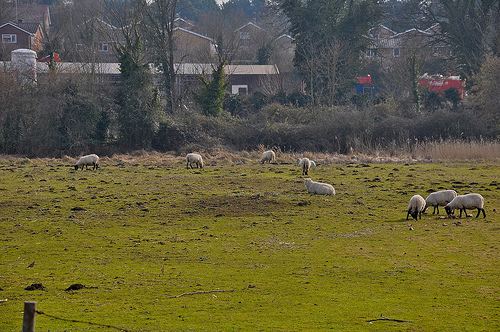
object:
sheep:
[299, 157, 312, 176]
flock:
[72, 149, 488, 221]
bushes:
[364, 116, 420, 154]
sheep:
[303, 177, 336, 196]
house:
[416, 72, 467, 101]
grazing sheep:
[185, 152, 204, 170]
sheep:
[73, 153, 100, 171]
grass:
[0, 157, 498, 330]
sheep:
[421, 189, 457, 215]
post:
[22, 300, 36, 332]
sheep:
[406, 194, 426, 221]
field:
[0, 154, 498, 329]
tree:
[89, 0, 161, 155]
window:
[2, 34, 17, 44]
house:
[145, 26, 216, 63]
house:
[364, 27, 460, 73]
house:
[233, 21, 273, 64]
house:
[55, 16, 125, 63]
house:
[0, 19, 45, 62]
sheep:
[260, 150, 275, 164]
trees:
[276, 0, 389, 112]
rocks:
[24, 282, 47, 291]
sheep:
[442, 193, 486, 219]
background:
[0, 0, 499, 159]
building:
[0, 5, 52, 42]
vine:
[110, 34, 160, 154]